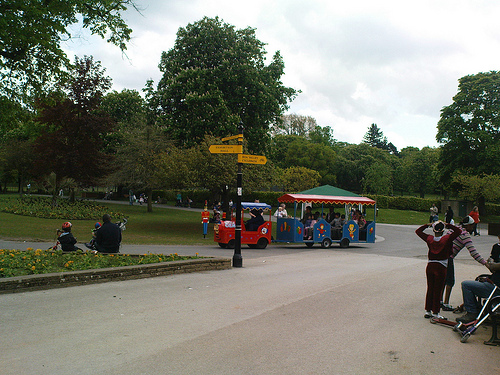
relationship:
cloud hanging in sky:
[0, 12, 500, 154] [20, 0, 497, 154]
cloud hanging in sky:
[80, 23, 176, 95] [20, 0, 497, 154]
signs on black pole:
[192, 126, 272, 180] [233, 164, 243, 267]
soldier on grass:
[194, 198, 219, 244] [142, 203, 199, 248]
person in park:
[88, 212, 125, 254] [3, 3, 498, 373]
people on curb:
[58, 212, 122, 251] [23, 250, 215, 254]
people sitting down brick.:
[35, 194, 147, 264] [105, 266, 139, 277]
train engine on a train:
[209, 196, 277, 251] [201, 178, 386, 247]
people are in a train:
[296, 196, 370, 249] [214, 185, 378, 249]